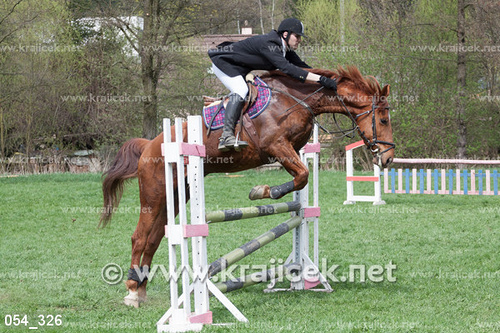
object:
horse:
[97, 64, 394, 308]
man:
[208, 18, 338, 152]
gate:
[161, 115, 320, 331]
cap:
[278, 18, 308, 39]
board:
[181, 142, 207, 157]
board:
[185, 224, 209, 238]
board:
[304, 207, 321, 218]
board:
[304, 143, 321, 153]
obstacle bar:
[205, 199, 303, 296]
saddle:
[203, 76, 272, 129]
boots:
[218, 93, 249, 152]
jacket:
[208, 29, 312, 84]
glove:
[317, 75, 337, 91]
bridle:
[207, 78, 374, 148]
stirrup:
[234, 110, 243, 152]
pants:
[212, 62, 248, 99]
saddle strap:
[242, 113, 270, 163]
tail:
[97, 138, 148, 229]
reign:
[332, 96, 375, 149]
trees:
[0, 1, 499, 173]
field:
[0, 166, 499, 331]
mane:
[300, 63, 381, 96]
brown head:
[354, 84, 395, 168]